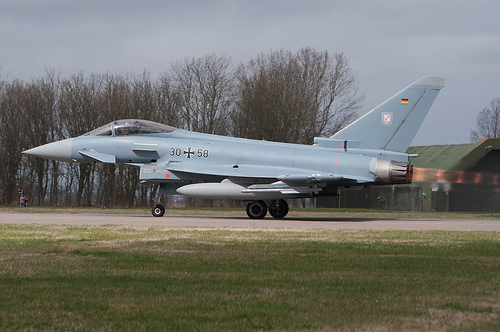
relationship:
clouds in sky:
[0, 0, 498, 88] [75, 15, 449, 95]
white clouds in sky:
[401, 35, 473, 72] [0, 0, 500, 136]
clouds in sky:
[0, 0, 498, 88] [51, 12, 180, 65]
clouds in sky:
[0, 0, 498, 88] [5, 7, 491, 132]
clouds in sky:
[0, 0, 497, 145] [0, 1, 497, 139]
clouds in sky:
[0, 0, 498, 88] [341, 21, 459, 91]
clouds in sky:
[0, 0, 498, 88] [58, 11, 173, 57]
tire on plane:
[268, 196, 289, 218] [47, 111, 387, 216]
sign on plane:
[151, 135, 229, 162] [70, 69, 392, 249]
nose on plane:
[22, 138, 89, 172] [16, 71, 444, 225]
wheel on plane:
[268, 199, 288, 219] [16, 71, 444, 225]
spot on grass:
[420, 313, 480, 327] [27, 215, 418, 270]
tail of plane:
[326, 77, 459, 149] [13, 66, 455, 208]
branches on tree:
[0, 48, 358, 209] [2, 48, 362, 205]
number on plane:
[165, 146, 183, 161] [16, 71, 444, 225]